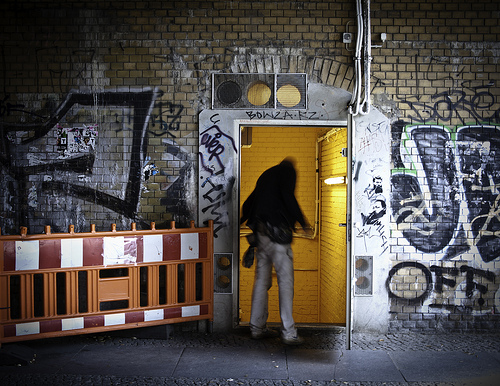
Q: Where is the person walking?
A: Into the building.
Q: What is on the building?
A: A plastic gate.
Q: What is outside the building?
A: A sidewalk.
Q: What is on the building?
A: Spray paint.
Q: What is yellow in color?
A: The room.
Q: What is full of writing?
A: The wall.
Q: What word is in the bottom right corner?
A: Off.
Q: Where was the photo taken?
A: In an alley.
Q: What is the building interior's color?
A: Yellow.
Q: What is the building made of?
A: Brick.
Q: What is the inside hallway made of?
A: Brick.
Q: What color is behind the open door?
A: Yellow.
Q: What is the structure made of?
A: Brick.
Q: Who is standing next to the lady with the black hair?
A: No one.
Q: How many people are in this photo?
A: One.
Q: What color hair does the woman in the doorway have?
A: Black.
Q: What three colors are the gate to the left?
A: Red, orange, white.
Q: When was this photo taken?
A: Daytime.